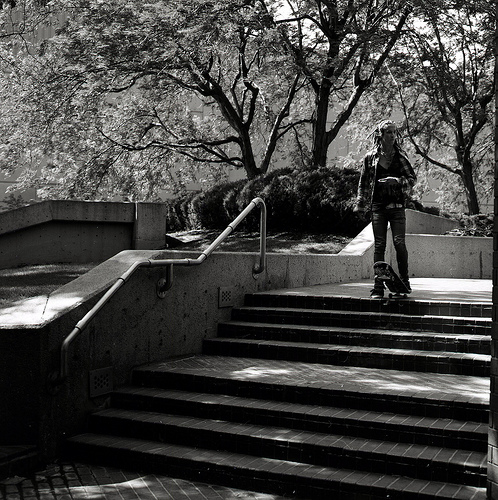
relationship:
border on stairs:
[282, 294, 455, 310] [64, 290, 496, 497]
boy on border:
[352, 120, 417, 300] [282, 294, 455, 310]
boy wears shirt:
[352, 120, 417, 300] [356, 150, 417, 207]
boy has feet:
[358, 122, 418, 298] [401, 272, 412, 293]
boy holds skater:
[358, 122, 418, 298] [373, 257, 402, 294]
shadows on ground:
[404, 280, 491, 303] [334, 266, 481, 371]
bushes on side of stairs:
[166, 165, 440, 236] [64, 290, 496, 497]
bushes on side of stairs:
[235, 172, 267, 231] [64, 290, 496, 497]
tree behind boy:
[441, 9, 491, 234] [350, 113, 413, 298]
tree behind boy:
[268, 1, 407, 166] [350, 113, 413, 298]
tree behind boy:
[51, 4, 304, 181] [350, 113, 413, 298]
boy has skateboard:
[352, 120, 417, 300] [374, 258, 410, 296]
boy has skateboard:
[352, 120, 417, 300] [372, 261, 411, 301]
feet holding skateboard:
[403, 281, 411, 290] [367, 250, 418, 306]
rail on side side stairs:
[60, 197, 268, 378] [39, 249, 258, 433]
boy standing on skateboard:
[352, 120, 417, 300] [369, 257, 412, 302]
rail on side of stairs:
[60, 197, 268, 378] [64, 368, 487, 500]